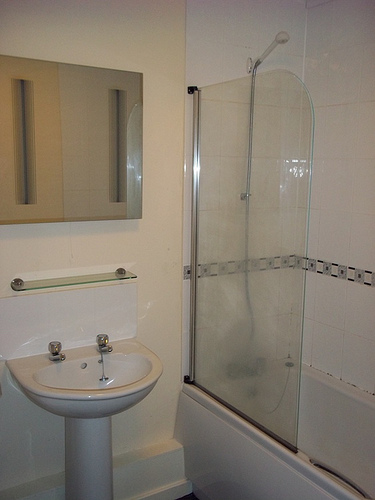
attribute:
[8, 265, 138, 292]
shelf — glass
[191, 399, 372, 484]
bathtub — white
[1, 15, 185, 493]
wall — white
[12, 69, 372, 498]
bathroom — scene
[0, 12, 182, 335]
wall — tile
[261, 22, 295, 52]
head — white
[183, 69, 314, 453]
wall — glass, clear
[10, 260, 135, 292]
shelf — clear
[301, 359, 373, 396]
mold — black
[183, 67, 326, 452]
glass — clear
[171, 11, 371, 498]
shower — white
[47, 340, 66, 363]
tap — silver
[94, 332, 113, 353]
tap — silver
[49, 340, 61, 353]
knob — grey, metal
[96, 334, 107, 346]
knob — grey, metal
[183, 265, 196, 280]
tile — black, white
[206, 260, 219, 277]
tile — black, white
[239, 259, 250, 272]
tile — black, white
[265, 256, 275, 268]
tile — black, white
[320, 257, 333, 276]
tile — black, white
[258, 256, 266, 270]
tile — white, black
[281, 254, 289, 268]
tile — white, black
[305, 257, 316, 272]
tile — white, black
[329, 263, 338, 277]
tile — white, black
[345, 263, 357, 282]
tile — white, black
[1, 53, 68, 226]
door — metal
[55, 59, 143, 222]
door — metal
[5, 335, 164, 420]
sink — white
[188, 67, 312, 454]
door — glass